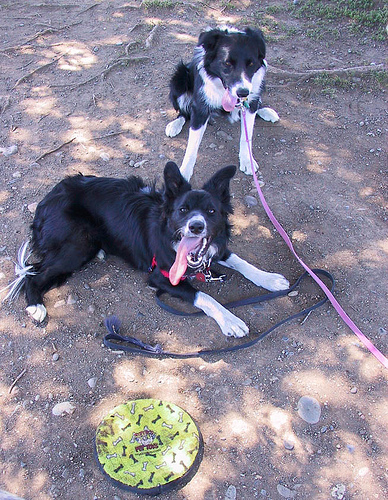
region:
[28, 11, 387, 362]
dogs on the ground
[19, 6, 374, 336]
two dogs on the ground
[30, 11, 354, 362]
dogs that are outside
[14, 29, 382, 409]
two dogs that are outside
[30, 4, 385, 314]
two black and white dogs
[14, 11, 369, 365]
black and white dogs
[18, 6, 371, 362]
dogs with their tongue out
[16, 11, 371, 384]
two dogs with their tongue out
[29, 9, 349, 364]
dogs on a leash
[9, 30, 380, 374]
dogs that are panting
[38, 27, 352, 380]
two dogs outside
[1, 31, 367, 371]
two dogs on the ground outside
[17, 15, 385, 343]
two dogs with their tongue hanging out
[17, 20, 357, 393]
two dogs on a leash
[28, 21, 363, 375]
two dogs with a leash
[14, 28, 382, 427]
two black and white dogs with their tongue out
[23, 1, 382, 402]
two black and white dogs with leashes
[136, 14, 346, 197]
a dog sitting down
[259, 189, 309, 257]
a long pink leash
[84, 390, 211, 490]
a yellow dog toy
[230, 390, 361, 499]
white rocks on the ground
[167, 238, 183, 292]
a log pink tongue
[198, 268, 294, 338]
white paws on a black dog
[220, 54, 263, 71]
brown eyes on a head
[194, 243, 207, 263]
sharp white teeth in a mouth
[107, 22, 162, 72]
tree roots in the dirt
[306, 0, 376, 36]
a patch of grass nearby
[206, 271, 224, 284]
a metal clip on the leash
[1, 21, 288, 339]
A pair of dogs on the ground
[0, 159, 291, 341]
A black and white dog laying down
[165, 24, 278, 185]
A black and white dog sitting on the ground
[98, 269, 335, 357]
A dark blue leash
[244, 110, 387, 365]
A bright pink leash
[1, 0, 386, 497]
A dirt path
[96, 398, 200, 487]
A round pet toy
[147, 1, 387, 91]
some grass on the ground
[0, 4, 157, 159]
some roots coming through the ground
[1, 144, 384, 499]
a large group of rocks scattered on the ground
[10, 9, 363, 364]
two dogs sitting in the dirt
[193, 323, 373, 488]
the sun is on the ground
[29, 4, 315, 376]
two dogs in the shade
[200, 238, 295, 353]
the paws are white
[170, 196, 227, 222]
the eyes are open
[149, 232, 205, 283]
the tongue is hanging out of the mouth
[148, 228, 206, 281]
the tongue is pink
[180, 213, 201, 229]
the nose is black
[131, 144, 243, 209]
the ears are pointed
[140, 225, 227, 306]
the tongue is long